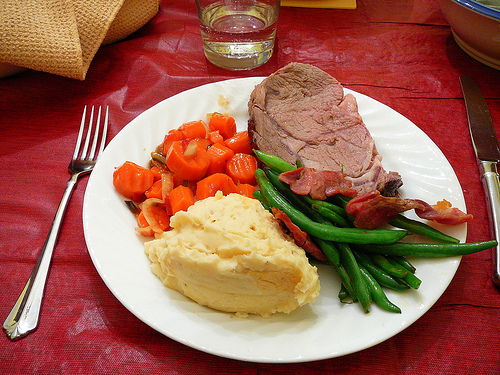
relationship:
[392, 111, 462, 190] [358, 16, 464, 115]
plate on table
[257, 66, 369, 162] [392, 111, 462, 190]
meat on plate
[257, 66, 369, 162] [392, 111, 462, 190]
meat in plate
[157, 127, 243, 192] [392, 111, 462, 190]
carrot on plate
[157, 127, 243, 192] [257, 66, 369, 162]
carrot near meat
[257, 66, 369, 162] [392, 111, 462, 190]
meat near plate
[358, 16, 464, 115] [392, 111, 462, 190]
table has plate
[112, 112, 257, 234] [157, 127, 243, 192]
carrot of carrot